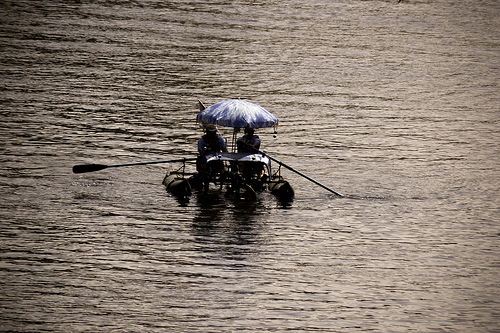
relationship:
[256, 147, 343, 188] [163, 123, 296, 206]
oar hanging off side boat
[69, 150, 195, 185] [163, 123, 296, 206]
oar hanging off side boat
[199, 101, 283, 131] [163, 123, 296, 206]
umbrella over boat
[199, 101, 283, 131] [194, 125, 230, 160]
umbrella over person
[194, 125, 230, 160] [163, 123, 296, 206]
person on boat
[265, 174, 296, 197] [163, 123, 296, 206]
cylinder holding up a boat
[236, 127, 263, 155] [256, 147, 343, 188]
person holding oar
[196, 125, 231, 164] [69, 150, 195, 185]
person holding oar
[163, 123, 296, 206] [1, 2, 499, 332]
boat on water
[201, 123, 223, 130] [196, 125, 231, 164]
hat on person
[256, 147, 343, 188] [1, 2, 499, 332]
oar in water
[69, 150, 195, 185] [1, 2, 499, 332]
oar above water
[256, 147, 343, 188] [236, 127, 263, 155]
oar held by person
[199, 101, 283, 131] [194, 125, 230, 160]
umbrella shading person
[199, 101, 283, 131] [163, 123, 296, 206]
umbrella on boat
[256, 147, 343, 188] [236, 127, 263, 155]
oar being used by person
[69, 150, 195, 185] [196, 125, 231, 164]
oar being used by person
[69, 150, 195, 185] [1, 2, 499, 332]
oar out of water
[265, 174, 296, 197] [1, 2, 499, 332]
cylinder in water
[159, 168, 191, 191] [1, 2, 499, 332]
cylinder in water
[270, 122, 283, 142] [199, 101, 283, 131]
balls hanging from umbrella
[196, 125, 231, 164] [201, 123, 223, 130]
person wearing hat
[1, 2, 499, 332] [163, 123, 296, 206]
water with a boat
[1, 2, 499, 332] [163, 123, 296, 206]
water under boat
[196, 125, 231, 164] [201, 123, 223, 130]
person wearing a hat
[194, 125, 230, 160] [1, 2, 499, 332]
person are on water